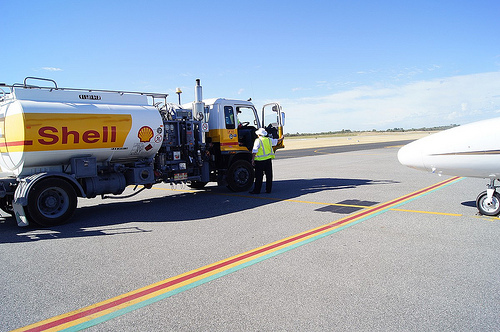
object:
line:
[257, 213, 354, 258]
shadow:
[1, 173, 405, 245]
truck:
[0, 85, 288, 227]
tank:
[0, 84, 160, 177]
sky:
[273, 17, 493, 75]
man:
[251, 127, 278, 195]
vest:
[253, 137, 275, 161]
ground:
[12, 223, 500, 300]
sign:
[8, 112, 122, 146]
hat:
[254, 127, 268, 136]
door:
[259, 102, 286, 149]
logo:
[136, 126, 154, 142]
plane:
[396, 117, 500, 219]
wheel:
[475, 190, 500, 217]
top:
[10, 76, 154, 106]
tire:
[29, 179, 76, 228]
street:
[273, 125, 493, 156]